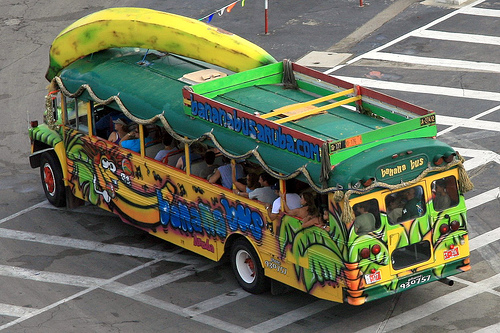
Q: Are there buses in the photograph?
A: Yes, there is a bus.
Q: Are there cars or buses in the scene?
A: Yes, there is a bus.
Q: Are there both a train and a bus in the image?
A: No, there is a bus but no trains.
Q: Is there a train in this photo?
A: No, there are no trains.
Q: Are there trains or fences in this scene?
A: No, there are no trains or fences.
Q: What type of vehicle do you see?
A: The vehicle is a bus.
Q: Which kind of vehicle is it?
A: The vehicle is a bus.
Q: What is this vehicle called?
A: This is a bus.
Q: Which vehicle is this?
A: This is a bus.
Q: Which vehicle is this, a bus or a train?
A: This is a bus.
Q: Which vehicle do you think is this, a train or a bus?
A: This is a bus.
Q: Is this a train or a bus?
A: This is a bus.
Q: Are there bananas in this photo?
A: Yes, there is a banana.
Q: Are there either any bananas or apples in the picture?
A: Yes, there is a banana.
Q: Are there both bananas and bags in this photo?
A: No, there is a banana but no bags.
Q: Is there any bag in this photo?
A: No, there are no bags.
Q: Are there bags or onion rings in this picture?
A: No, there are no bags or onion rings.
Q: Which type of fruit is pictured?
A: The fruit is a banana.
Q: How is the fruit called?
A: The fruit is a banana.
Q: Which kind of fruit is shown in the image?
A: The fruit is a banana.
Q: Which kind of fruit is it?
A: The fruit is a banana.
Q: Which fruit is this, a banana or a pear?
A: This is a banana.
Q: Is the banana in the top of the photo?
A: Yes, the banana is in the top of the image.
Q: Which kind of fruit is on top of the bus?
A: The fruit is a banana.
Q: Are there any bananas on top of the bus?
A: Yes, there is a banana on top of the bus.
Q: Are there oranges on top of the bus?
A: No, there is a banana on top of the bus.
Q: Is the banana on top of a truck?
A: No, the banana is on top of a bus.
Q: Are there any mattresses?
A: No, there are no mattresses.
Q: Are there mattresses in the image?
A: No, there are no mattresses.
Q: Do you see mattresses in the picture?
A: No, there are no mattresses.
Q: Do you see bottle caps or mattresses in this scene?
A: No, there are no mattresses or bottle caps.